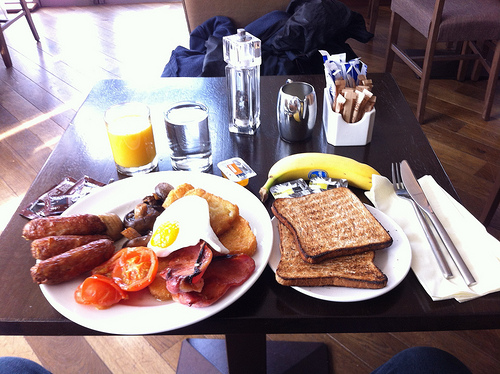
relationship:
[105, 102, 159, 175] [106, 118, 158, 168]
glass of orange juice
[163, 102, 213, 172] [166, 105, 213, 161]
glass of water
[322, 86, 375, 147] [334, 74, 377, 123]
container with sugar packets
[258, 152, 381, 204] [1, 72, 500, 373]
banana on table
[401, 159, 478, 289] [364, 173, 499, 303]
knife on napkin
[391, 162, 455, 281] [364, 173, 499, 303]
fork on napkin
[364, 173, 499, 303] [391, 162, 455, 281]
napkin under fork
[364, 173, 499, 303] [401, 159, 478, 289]
napkin under knife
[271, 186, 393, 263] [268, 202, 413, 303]
toast on plate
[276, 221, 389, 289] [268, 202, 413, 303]
toast on plate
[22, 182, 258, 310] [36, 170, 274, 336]
foods on plate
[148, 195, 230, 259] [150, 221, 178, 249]
egg with yolk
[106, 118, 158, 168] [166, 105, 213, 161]
orange juice next to water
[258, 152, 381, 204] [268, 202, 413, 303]
banana next to plate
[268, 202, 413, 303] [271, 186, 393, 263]
plate of toast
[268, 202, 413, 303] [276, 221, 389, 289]
plate of toast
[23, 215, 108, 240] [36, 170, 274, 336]
sausage on plate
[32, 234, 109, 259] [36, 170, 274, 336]
sausage on plate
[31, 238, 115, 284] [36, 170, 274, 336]
sausage on plate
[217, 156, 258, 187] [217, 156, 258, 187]
container of container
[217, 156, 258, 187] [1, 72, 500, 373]
container on table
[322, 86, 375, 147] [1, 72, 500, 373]
container on table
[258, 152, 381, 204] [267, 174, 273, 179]
banana with spot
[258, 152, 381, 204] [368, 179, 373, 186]
banana with spot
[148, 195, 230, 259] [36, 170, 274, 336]
egg on plate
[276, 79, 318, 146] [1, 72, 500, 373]
pitcher on table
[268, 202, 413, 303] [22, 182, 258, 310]
plate filled with foods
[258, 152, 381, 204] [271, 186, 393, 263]
banana above toast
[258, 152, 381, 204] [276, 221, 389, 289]
banana above toast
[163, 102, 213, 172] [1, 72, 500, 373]
glass on table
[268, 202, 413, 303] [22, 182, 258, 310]
plate of foods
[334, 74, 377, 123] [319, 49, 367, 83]
sugar packets and sweetener packets